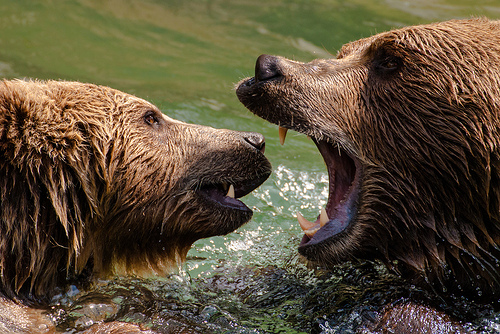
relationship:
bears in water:
[54, 49, 482, 295] [208, 275, 281, 310]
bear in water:
[45, 68, 263, 237] [185, 261, 257, 302]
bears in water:
[41, 56, 437, 257] [237, 269, 299, 308]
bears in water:
[81, 64, 444, 272] [237, 269, 299, 308]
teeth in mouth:
[274, 119, 289, 148] [257, 95, 350, 246]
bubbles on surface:
[223, 262, 265, 302] [203, 258, 312, 323]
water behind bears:
[76, 22, 248, 108] [54, 49, 482, 295]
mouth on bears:
[225, 57, 403, 278] [43, 21, 490, 311]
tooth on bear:
[260, 106, 317, 172] [216, 52, 446, 270]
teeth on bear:
[272, 202, 340, 258] [230, 51, 473, 321]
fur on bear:
[16, 87, 76, 187] [22, 73, 254, 300]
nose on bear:
[245, 46, 306, 76] [258, 51, 483, 310]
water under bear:
[193, 220, 331, 327] [258, 51, 483, 310]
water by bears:
[106, 6, 247, 133] [54, 49, 482, 295]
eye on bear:
[348, 16, 469, 127] [247, 36, 477, 223]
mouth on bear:
[255, 120, 380, 300] [204, 43, 462, 285]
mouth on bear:
[167, 129, 257, 208] [33, 80, 250, 270]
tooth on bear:
[274, 190, 343, 259] [228, 13, 498, 333]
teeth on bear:
[272, 210, 364, 277] [234, 20, 463, 267]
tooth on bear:
[214, 150, 253, 185] [33, 85, 223, 245]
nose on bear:
[245, 46, 306, 76] [227, 46, 495, 281]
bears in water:
[49, 33, 416, 196] [73, 16, 293, 144]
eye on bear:
[348, 16, 469, 127] [234, 20, 463, 267]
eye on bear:
[128, 110, 178, 142] [1, 65, 278, 326]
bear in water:
[1, 65, 278, 326] [1, 1, 498, 332]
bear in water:
[228, 13, 498, 333] [1, 1, 498, 332]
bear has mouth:
[228, 13, 498, 333] [255, 120, 380, 300]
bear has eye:
[1, 65, 278, 326] [128, 110, 178, 142]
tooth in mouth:
[309, 203, 336, 230] [222, 78, 374, 278]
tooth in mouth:
[289, 208, 315, 239] [222, 78, 374, 278]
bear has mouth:
[228, 13, 498, 333] [222, 78, 374, 278]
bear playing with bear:
[1, 65, 278, 326] [228, 13, 498, 333]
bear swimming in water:
[228, 13, 498, 333] [1, 1, 498, 332]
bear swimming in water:
[1, 65, 278, 326] [1, 1, 498, 332]